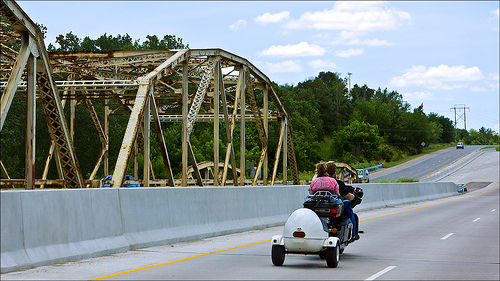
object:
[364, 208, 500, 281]
line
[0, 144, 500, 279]
road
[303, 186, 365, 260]
motorcyle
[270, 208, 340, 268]
trailer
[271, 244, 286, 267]
wheels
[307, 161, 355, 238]
people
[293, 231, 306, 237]
tail light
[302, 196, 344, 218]
storage bin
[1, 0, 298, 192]
bridge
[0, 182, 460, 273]
barrier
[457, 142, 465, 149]
car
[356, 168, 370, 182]
car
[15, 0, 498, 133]
sky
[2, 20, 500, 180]
trees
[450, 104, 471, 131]
structure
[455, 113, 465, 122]
power cables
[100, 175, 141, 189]
car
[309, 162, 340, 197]
woman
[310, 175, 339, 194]
shirt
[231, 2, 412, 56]
clouds